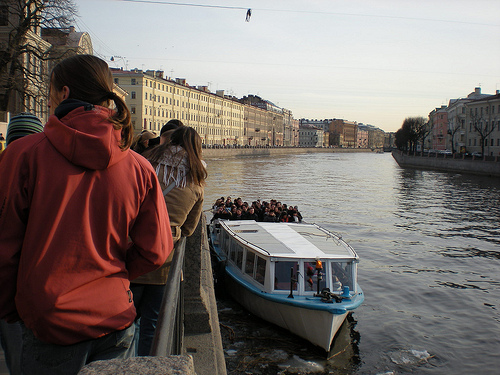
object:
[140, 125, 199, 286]
people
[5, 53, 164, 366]
person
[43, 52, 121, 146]
head